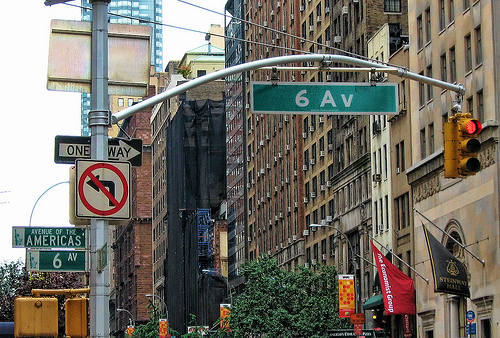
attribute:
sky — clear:
[12, 100, 119, 202]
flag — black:
[420, 219, 471, 299]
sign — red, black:
[70, 164, 135, 214]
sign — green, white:
[249, 81, 399, 116]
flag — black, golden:
[348, 233, 458, 325]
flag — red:
[371, 244, 413, 314]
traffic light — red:
[458, 112, 485, 137]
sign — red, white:
[239, 79, 409, 125]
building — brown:
[228, 5, 418, 272]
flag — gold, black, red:
[370, 242, 417, 316]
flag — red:
[361, 234, 418, 319]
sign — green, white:
[215, 58, 429, 133]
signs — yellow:
[0, 112, 168, 306]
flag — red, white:
[368, 237, 415, 324]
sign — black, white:
[54, 137, 144, 169]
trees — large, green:
[220, 246, 341, 333]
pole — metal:
[411, 207, 488, 267]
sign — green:
[238, 73, 418, 128]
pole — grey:
[251, 59, 404, 76]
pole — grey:
[110, 49, 467, 130]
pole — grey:
[83, 3, 113, 336]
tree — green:
[225, 246, 366, 337]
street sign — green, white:
[254, 73, 398, 115]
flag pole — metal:
[408, 206, 488, 275]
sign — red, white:
[74, 156, 130, 221]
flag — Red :
[361, 228, 424, 322]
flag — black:
[409, 202, 474, 298]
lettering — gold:
[438, 275, 469, 292]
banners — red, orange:
[124, 273, 355, 336]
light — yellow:
[17, 280, 87, 331]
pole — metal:
[84, 1, 119, 336]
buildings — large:
[130, 14, 498, 333]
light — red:
[442, 108, 482, 182]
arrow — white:
[60, 136, 144, 166]